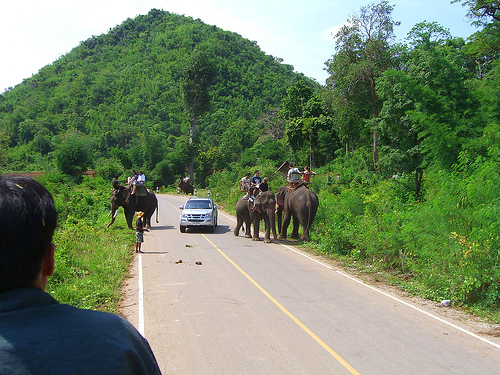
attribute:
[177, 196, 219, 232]
truck — small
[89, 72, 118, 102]
leaves — GREEN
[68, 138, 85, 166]
leaves — green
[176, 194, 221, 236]
truck — small